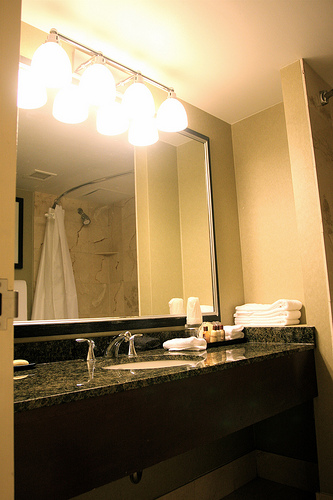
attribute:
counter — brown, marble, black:
[0, 309, 324, 420]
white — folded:
[223, 287, 307, 325]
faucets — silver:
[47, 314, 150, 354]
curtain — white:
[36, 206, 80, 321]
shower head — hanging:
[76, 198, 97, 231]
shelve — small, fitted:
[93, 240, 120, 266]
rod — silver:
[47, 157, 135, 212]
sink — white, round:
[104, 339, 208, 377]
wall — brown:
[249, 84, 317, 287]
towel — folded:
[158, 332, 213, 355]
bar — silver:
[56, 23, 197, 83]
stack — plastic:
[178, 288, 207, 329]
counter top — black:
[27, 322, 284, 413]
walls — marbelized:
[44, 184, 142, 325]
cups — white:
[161, 277, 233, 341]